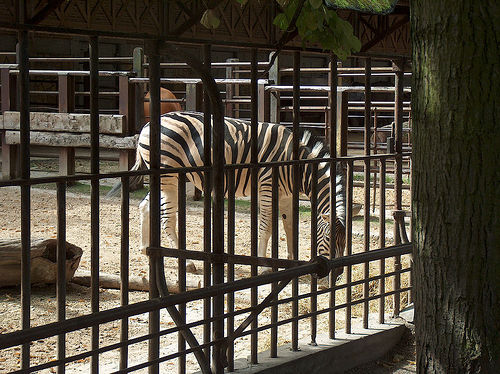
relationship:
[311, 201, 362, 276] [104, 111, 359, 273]
head of a zebra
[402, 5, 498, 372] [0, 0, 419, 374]
tree outside of bars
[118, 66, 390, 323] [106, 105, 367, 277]
bars of zrbra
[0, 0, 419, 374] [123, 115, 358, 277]
bars of zebra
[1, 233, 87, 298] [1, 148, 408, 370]
log on ground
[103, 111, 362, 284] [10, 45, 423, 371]
zebra in cage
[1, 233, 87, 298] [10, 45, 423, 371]
log in cage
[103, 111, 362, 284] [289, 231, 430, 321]
zebra eating hay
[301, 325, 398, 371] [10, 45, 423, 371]
curb of cage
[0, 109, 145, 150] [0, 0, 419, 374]
slats alongside of bars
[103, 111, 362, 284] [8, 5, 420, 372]
zebra behind bars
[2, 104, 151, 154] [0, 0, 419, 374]
slats on bars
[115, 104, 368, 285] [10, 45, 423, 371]
zebra in cage